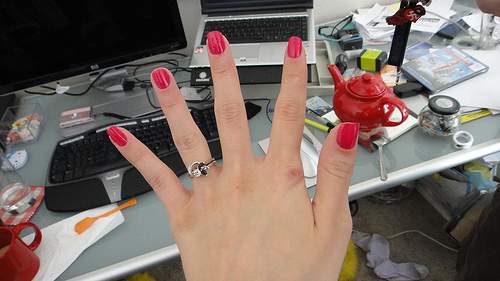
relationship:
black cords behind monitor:
[22, 51, 212, 108] [0, 0, 187, 95]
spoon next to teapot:
[370, 134, 388, 182] [328, 60, 407, 152]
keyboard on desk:
[42, 106, 222, 213] [0, 1, 497, 280]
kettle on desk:
[327, 64, 410, 131] [0, 1, 497, 280]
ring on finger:
[187, 156, 216, 176] [132, 53, 224, 190]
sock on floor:
[350, 232, 431, 281] [105, 186, 461, 279]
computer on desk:
[187, 1, 317, 68] [0, 1, 497, 280]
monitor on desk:
[3, 5, 185, 103] [0, 1, 497, 280]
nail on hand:
[336, 121, 360, 149] [103, 29, 364, 279]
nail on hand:
[285, 37, 305, 57] [103, 29, 364, 279]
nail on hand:
[207, 31, 226, 53] [103, 29, 364, 279]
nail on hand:
[152, 69, 172, 90] [103, 29, 364, 279]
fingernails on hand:
[104, 125, 127, 147] [103, 29, 364, 279]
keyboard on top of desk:
[42, 106, 222, 213] [0, 1, 497, 280]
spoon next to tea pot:
[370, 134, 388, 182] [326, 60, 408, 133]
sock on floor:
[350, 224, 431, 279] [140, 186, 462, 276]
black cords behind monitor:
[22, 59, 212, 108] [55, 0, 203, 111]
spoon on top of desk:
[371, 131, 390, 181] [0, 1, 497, 280]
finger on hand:
[201, 29, 251, 164] [103, 29, 364, 279]